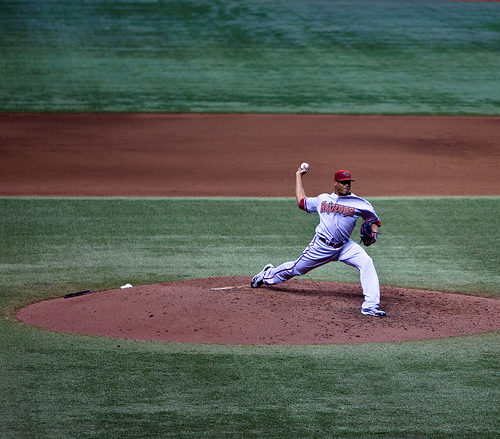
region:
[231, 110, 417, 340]
baseball player in uniform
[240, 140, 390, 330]
pitcher with ball in hand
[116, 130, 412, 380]
player on brown mound of dirt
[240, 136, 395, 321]
player with legs in a wide stance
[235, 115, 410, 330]
player with gloved hand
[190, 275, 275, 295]
white line on top of mound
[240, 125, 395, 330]
pitcher with arm behind back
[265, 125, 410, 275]
player wearing a red cap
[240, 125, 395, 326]
player in grey uniform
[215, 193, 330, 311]
toe pointed into ground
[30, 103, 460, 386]
A pitcher throwing the baseball.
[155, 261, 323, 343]
The pitcher's mound.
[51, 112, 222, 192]
Red dirt in a baseball field.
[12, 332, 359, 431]
Green grass in baseball field.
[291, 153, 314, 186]
A baseball in the right hand.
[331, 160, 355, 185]
Red baseball team cap.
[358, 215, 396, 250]
Pitcher's baseball glove.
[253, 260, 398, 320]
A pair of baseball cleats..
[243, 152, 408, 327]
Man in baseball uniform.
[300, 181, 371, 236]
Short sleeve shirt with red letters.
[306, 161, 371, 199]
Man wearing red hat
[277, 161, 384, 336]
Baseball player is wearing gray uniform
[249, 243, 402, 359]
Man wearing tennis shoes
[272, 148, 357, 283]
Man has baseball in right hand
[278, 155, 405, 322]
Man throwing baseball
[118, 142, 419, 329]
Man standing on pitcher's mound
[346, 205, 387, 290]
Man has mitt in left hand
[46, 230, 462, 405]
Mound in middle of green field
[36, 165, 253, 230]
White lines on field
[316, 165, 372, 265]
Uniform says Arizona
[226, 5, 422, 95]
a green part of the pitch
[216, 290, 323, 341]
brown part of the field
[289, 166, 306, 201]
right arm of the player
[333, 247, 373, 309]
part of the player's white pant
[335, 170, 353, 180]
red part of a cap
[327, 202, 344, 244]
part of a white top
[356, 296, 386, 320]
a sport shoe on the left foot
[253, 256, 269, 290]
a shoe on the right foot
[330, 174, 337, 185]
ear of the player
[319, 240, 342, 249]
part of a belt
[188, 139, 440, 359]
a baseball player throwing a ball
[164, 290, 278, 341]
a dirt mound on the baseball field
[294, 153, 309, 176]
a hand holding a baseball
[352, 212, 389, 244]
a hand holding a mitt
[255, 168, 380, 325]
a man wearing a red hat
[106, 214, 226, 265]
lush green grass on the field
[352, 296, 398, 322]
a sneaker covering a foot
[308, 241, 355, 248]
a black belt holding up pants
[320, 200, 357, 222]
a team logo on a jersey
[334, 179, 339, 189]
a brown ear on a head